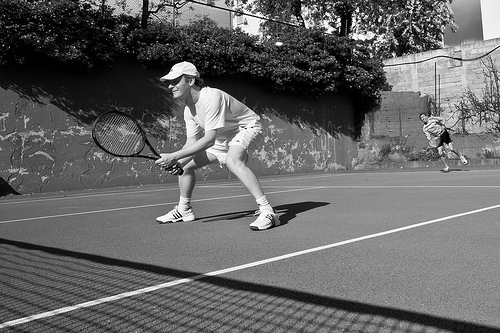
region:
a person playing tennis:
[66, 48, 320, 284]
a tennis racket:
[76, 106, 207, 202]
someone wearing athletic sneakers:
[108, 53, 318, 281]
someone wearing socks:
[114, 56, 306, 263]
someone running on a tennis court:
[403, 88, 498, 205]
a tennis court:
[39, 117, 475, 331]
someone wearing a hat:
[136, 57, 215, 117]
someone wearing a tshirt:
[128, 54, 243, 168]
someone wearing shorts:
[135, 31, 290, 221]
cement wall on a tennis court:
[15, 73, 450, 189]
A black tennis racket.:
[88, 110, 182, 175]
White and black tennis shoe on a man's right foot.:
[156, 203, 196, 223]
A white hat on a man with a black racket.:
[157, 59, 198, 83]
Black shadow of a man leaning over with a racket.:
[193, 200, 330, 226]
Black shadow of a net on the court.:
[1, 238, 492, 332]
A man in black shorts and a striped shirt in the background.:
[418, 112, 470, 173]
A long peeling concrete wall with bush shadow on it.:
[0, 60, 362, 193]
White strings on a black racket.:
[96, 118, 142, 150]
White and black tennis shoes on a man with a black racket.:
[156, 205, 283, 230]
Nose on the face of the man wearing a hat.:
[166, 81, 174, 90]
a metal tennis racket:
[90, 111, 167, 167]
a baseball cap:
[160, 58, 198, 78]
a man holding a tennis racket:
[90, 60, 280, 227]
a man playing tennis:
[418, 110, 468, 170]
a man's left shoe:
[247, 212, 277, 228]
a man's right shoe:
[156, 205, 194, 221]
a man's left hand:
[153, 150, 178, 166]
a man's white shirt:
[180, 87, 263, 132]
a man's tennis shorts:
[206, 120, 262, 158]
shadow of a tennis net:
[0, 237, 499, 330]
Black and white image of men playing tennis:
[2, 1, 499, 331]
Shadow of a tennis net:
[0, 236, 497, 331]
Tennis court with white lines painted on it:
[1, 166, 498, 330]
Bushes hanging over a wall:
[1, 0, 391, 102]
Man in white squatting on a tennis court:
[90, 60, 280, 231]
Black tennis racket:
[90, 106, 184, 177]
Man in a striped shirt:
[416, 111, 469, 173]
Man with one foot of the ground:
[418, 110, 468, 173]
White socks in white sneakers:
[152, 195, 282, 230]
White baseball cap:
[158, 59, 201, 81]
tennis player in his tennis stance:
[157, 59, 280, 231]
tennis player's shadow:
[199, 199, 333, 224]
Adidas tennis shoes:
[247, 212, 283, 229]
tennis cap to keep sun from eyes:
[158, 59, 198, 81]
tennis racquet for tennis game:
[89, 109, 185, 177]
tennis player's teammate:
[417, 110, 467, 173]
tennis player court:
[3, 233, 499, 330]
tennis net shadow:
[0, 238, 497, 328]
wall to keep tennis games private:
[383, 43, 492, 111]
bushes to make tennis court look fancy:
[3, 2, 367, 108]